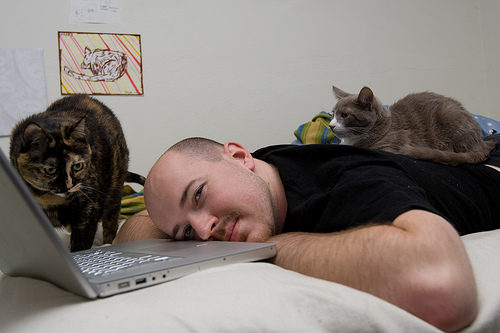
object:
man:
[110, 138, 500, 332]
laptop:
[0, 144, 277, 299]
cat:
[327, 84, 496, 164]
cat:
[10, 95, 130, 253]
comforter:
[0, 217, 499, 331]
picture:
[57, 31, 145, 97]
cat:
[63, 45, 127, 81]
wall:
[0, 1, 499, 193]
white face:
[329, 117, 347, 138]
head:
[142, 138, 286, 243]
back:
[250, 143, 497, 228]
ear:
[225, 141, 255, 172]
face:
[143, 162, 274, 242]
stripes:
[59, 33, 143, 98]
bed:
[0, 219, 499, 333]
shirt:
[250, 144, 500, 237]